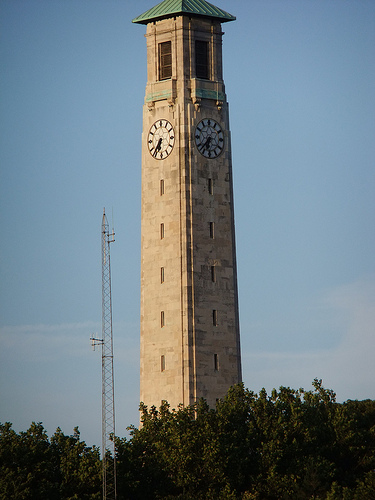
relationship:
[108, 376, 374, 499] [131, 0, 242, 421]
tree in front of tower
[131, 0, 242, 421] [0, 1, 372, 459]
tower behind sky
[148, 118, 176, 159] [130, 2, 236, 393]
clock on tower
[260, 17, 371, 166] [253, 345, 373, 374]
sky with clouds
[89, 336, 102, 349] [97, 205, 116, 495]
support of tower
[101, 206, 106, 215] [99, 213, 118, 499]
point of tower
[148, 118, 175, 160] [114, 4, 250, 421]
clock in tower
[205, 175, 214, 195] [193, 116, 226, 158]
windows below clock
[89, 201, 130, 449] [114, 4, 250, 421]
tower by tower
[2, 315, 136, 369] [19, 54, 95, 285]
clouds in sky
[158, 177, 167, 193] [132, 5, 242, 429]
window on side structure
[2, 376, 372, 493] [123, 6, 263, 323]
trees in front of tower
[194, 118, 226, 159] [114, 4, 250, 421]
clock on side of tower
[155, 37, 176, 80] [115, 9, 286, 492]
window on tower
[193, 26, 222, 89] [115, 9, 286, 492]
window on tower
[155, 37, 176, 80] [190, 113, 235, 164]
window below clock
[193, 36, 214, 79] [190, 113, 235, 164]
window below clock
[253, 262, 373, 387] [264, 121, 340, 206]
clouds in sky